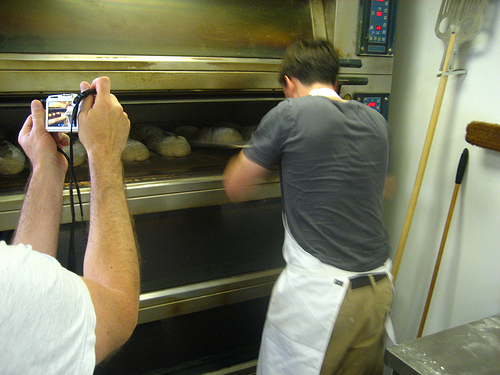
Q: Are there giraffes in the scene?
A: No, there are no giraffes.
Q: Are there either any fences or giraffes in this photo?
A: No, there are no giraffes or fences.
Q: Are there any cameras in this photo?
A: Yes, there is a camera.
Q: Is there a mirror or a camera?
A: Yes, there is a camera.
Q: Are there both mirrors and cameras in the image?
A: No, there is a camera but no mirrors.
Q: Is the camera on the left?
A: Yes, the camera is on the left of the image.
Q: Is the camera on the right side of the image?
A: No, the camera is on the left of the image.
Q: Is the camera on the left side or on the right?
A: The camera is on the left of the image.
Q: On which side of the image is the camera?
A: The camera is on the left of the image.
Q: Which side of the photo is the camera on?
A: The camera is on the left of the image.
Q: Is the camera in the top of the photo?
A: Yes, the camera is in the top of the image.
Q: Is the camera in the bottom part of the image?
A: No, the camera is in the top of the image.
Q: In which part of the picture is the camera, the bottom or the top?
A: The camera is in the top of the image.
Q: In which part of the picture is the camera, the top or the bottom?
A: The camera is in the top of the image.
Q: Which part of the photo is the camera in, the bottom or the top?
A: The camera is in the top of the image.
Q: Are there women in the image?
A: No, there are no women.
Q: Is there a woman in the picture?
A: No, there are no women.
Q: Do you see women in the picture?
A: No, there are no women.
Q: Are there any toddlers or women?
A: No, there are no women or toddlers.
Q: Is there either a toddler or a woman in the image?
A: No, there are no women or toddlers.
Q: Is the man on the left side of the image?
A: Yes, the man is on the left of the image.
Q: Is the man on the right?
A: No, the man is on the left of the image.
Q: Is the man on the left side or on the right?
A: The man is on the left of the image.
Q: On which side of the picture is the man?
A: The man is on the left of the image.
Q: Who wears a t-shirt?
A: The man wears a t-shirt.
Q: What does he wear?
A: The man wears a t-shirt.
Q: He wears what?
A: The man wears a t-shirt.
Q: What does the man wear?
A: The man wears a t-shirt.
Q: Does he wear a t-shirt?
A: Yes, the man wears a t-shirt.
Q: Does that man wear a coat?
A: No, the man wears a t-shirt.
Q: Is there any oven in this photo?
A: Yes, there is an oven.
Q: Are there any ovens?
A: Yes, there is an oven.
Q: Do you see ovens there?
A: Yes, there is an oven.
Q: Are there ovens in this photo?
A: Yes, there is an oven.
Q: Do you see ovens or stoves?
A: Yes, there is an oven.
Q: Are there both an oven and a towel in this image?
A: No, there is an oven but no towels.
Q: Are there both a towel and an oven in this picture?
A: No, there is an oven but no towels.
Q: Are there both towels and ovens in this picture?
A: No, there is an oven but no towels.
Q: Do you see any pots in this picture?
A: No, there are no pots.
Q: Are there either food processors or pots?
A: No, there are no pots or food processors.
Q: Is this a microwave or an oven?
A: This is an oven.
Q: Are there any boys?
A: No, there are no boys.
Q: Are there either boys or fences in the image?
A: No, there are no boys or fences.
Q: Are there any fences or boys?
A: No, there are no boys or fences.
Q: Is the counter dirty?
A: Yes, the counter is dirty.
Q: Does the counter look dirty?
A: Yes, the counter is dirty.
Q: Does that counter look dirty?
A: Yes, the counter is dirty.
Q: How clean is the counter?
A: The counter is dirty.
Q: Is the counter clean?
A: No, the counter is dirty.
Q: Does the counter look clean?
A: No, the counter is dirty.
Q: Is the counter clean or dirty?
A: The counter is dirty.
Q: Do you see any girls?
A: No, there are no girls.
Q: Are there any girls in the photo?
A: No, there are no girls.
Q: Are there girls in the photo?
A: No, there are no girls.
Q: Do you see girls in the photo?
A: No, there are no girls.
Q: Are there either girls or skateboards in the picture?
A: No, there are no girls or skateboards.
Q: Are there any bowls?
A: No, there are no bowls.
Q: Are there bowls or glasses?
A: No, there are no bowls or glasses.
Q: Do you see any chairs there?
A: No, there are no chairs.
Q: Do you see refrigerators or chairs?
A: No, there are no chairs or refrigerators.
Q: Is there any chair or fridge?
A: No, there are no chairs or refrigerators.